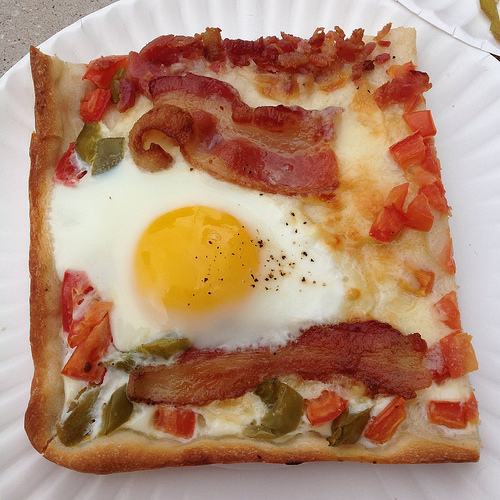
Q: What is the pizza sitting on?
A: A white plate.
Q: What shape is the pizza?
A: Square.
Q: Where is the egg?
A: On top of the pizza.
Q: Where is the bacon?
A: On top of the pizza.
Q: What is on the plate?
A: A piece of pizza.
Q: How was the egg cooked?
A: Sunny side up.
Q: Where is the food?
A: On the plate.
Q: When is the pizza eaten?
A: For breakfast.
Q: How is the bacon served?
A: Cooked atop bread.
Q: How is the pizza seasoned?
A: With pepper.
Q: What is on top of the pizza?
A: An egg.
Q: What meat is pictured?
A: Bacon.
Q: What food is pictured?
A: A pizza.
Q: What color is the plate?
A: White.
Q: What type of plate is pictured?
A: A paper plate.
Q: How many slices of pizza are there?
A: One.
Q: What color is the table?
A: Grey.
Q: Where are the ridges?
A: On the paper plate.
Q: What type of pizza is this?
A: A breakfast pizza.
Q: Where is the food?
A: On plate.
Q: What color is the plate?
A: White.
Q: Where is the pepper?
A: On egg.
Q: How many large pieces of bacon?
A: 2.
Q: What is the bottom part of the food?
A: Bread.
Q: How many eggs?
A: 1.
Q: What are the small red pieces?
A: Tomatoes.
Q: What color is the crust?
A: Brown.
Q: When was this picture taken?
A: Daytime.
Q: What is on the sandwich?
A: Egg and bacon.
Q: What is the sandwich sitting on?
A: A paper plate.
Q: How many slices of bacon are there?
A: Three.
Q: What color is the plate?
A: White.